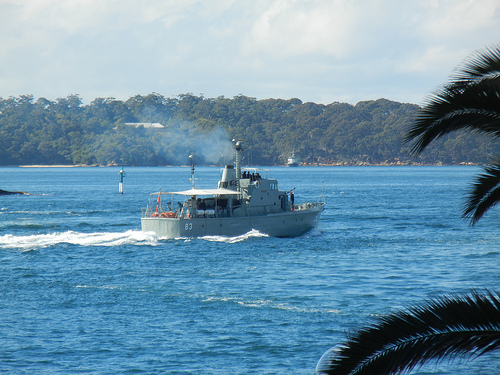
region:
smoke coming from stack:
[155, 91, 258, 169]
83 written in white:
[175, 220, 197, 237]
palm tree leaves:
[369, 73, 486, 371]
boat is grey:
[222, 153, 294, 235]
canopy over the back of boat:
[149, 164, 265, 216]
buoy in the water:
[86, 149, 127, 194]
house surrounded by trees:
[113, 111, 205, 153]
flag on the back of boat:
[129, 188, 177, 217]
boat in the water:
[284, 132, 327, 172]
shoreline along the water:
[27, 159, 107, 173]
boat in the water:
[121, 132, 303, 317]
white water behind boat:
[80, 215, 145, 250]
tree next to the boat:
[412, 65, 487, 145]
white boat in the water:
[158, 130, 328, 281]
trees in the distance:
[158, 91, 218, 156]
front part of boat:
[298, 190, 333, 244]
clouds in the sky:
[263, 32, 347, 69]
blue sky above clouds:
[131, 23, 240, 80]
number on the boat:
[160, 211, 210, 244]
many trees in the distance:
[65, 95, 190, 182]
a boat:
[127, 84, 377, 371]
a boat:
[180, 112, 315, 354]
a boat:
[131, 31, 275, 332]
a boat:
[227, 157, 332, 368]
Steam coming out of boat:
[160, 125, 301, 253]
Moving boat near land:
[75, 103, 350, 281]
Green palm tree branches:
[342, 82, 496, 374]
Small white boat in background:
[280, 142, 306, 172]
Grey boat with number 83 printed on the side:
[147, 167, 337, 246]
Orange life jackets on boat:
[148, 191, 179, 228]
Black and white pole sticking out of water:
[109, 162, 132, 202]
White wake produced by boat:
[4, 215, 139, 281]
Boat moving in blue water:
[142, 156, 337, 339]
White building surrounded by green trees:
[51, 99, 206, 163]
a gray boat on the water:
[121, 137, 339, 270]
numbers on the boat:
[180, 217, 200, 236]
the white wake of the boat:
[0, 220, 175, 263]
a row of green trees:
[0, 89, 499, 172]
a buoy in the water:
[109, 165, 130, 200]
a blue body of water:
[2, 157, 498, 373]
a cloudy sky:
[0, 0, 498, 107]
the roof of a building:
[107, 114, 170, 135]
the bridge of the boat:
[264, 177, 284, 194]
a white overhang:
[142, 181, 244, 208]